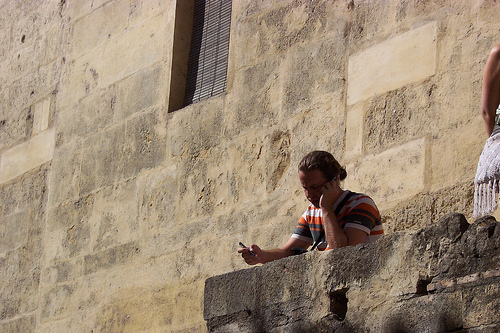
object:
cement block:
[79, 190, 144, 252]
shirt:
[291, 189, 385, 251]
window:
[176, 7, 227, 99]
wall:
[352, 97, 456, 161]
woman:
[471, 35, 499, 217]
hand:
[315, 176, 342, 211]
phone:
[236, 242, 258, 260]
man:
[237, 149, 385, 267]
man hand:
[237, 243, 263, 266]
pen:
[238, 241, 258, 259]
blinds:
[185, 0, 231, 105]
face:
[300, 169, 325, 206]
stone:
[190, 262, 262, 329]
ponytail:
[342, 162, 348, 180]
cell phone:
[323, 169, 341, 189]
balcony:
[203, 213, 498, 332]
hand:
[238, 242, 265, 265]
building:
[1, 2, 499, 332]